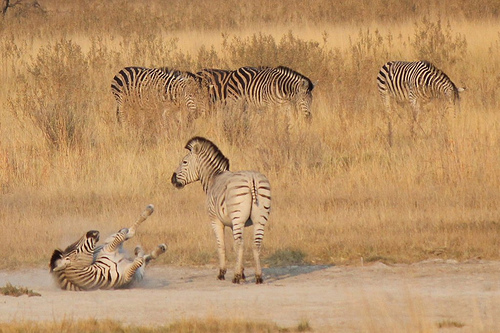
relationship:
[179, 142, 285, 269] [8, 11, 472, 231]
zebra on ground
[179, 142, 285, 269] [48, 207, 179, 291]
zebra looking at zebra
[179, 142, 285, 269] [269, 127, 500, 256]
zebra eating grassland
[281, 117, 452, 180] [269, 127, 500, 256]
weeds in grassland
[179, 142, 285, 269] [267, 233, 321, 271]
zebra casting shadow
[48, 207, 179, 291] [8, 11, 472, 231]
zebra lying on ground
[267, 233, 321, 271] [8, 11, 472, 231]
shadow on ground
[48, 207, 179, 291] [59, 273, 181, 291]
zebra rolling on its back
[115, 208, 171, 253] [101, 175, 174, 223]
hooves in air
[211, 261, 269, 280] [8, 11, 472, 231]
hooves standing on ground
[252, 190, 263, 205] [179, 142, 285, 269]
tail of zebra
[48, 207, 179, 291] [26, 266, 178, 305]
zebra lying on side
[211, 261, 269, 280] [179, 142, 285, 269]
hoot of zebra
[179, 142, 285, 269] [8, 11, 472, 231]
zebra on savanna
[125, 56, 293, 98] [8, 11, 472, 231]
zebras on savanna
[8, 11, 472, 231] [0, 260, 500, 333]
savanna above path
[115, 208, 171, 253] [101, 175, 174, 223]
zebralegs in air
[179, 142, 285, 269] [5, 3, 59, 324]
zebra looking left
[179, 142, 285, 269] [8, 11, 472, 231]
zebra in bush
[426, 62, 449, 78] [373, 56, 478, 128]
mane on zebra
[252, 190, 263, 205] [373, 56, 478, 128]
tail on zebra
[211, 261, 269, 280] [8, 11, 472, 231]
hooves on ground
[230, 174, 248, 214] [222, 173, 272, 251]
stripes on hindquarters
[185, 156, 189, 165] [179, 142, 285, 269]
eyes on zebra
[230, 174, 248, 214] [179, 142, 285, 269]
stripes on zebra